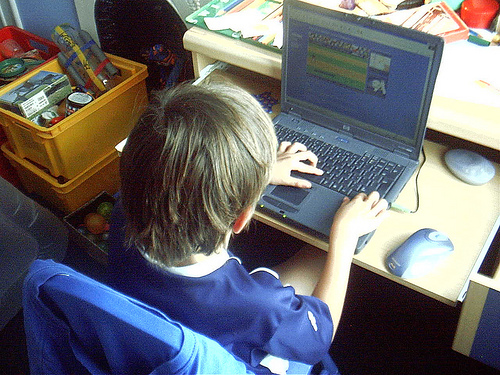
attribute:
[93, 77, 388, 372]
boy — young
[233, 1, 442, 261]
laptop — open, ope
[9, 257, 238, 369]
shirt — blue, draped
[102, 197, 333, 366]
shirt — blue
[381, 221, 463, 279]
mouse — wireless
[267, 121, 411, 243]
keyboard — black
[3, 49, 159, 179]
bin — yellow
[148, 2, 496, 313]
desk — white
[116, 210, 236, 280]
collar — white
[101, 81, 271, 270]
hair — fallig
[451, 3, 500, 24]
cotaier — red